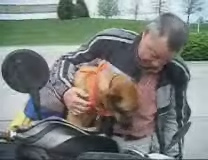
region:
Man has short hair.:
[153, 15, 194, 61]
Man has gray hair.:
[154, 16, 188, 56]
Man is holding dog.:
[82, 61, 128, 136]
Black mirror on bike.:
[3, 57, 50, 114]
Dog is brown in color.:
[77, 59, 126, 120]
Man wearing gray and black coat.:
[81, 36, 183, 103]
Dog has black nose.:
[121, 114, 134, 139]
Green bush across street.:
[184, 31, 207, 54]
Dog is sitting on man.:
[70, 90, 102, 150]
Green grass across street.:
[31, 22, 78, 35]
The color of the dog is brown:
[7, 62, 142, 132]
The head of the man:
[135, 8, 189, 71]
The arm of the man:
[47, 33, 104, 116]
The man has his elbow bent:
[39, 35, 80, 79]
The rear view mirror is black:
[1, 47, 50, 127]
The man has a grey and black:
[43, 27, 193, 150]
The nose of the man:
[149, 57, 165, 68]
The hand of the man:
[57, 86, 91, 117]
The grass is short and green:
[4, 20, 89, 39]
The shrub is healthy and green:
[181, 30, 207, 60]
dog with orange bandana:
[65, 49, 144, 139]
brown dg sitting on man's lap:
[60, 54, 153, 148]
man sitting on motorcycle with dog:
[47, 3, 199, 150]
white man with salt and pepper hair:
[128, 6, 188, 74]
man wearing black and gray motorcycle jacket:
[54, 6, 205, 157]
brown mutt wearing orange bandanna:
[65, 54, 152, 142]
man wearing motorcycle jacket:
[50, 12, 193, 150]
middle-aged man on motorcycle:
[48, 5, 197, 143]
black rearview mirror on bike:
[4, 46, 73, 126]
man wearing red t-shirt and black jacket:
[69, 6, 199, 150]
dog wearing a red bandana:
[79, 67, 134, 117]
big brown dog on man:
[110, 72, 137, 127]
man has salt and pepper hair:
[149, 24, 179, 48]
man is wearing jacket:
[160, 83, 169, 99]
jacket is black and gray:
[162, 84, 189, 114]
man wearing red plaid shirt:
[142, 79, 153, 101]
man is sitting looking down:
[132, 26, 197, 74]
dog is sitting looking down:
[92, 74, 134, 125]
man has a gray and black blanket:
[31, 126, 91, 151]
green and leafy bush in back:
[187, 37, 203, 56]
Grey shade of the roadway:
[190, 62, 207, 158]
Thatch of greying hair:
[149, 10, 190, 52]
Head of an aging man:
[135, 10, 190, 70]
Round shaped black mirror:
[1, 45, 52, 118]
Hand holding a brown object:
[64, 57, 142, 130]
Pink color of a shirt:
[137, 76, 155, 134]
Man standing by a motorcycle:
[0, 22, 205, 156]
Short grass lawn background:
[1, 19, 99, 42]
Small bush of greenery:
[187, 28, 206, 58]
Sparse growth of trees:
[56, 1, 205, 22]